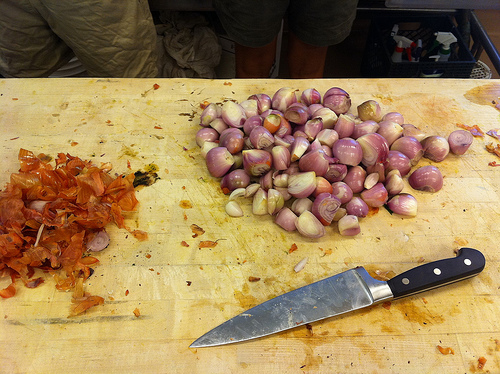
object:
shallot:
[449, 123, 471, 153]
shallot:
[293, 208, 324, 239]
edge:
[188, 265, 366, 346]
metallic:
[191, 263, 364, 351]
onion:
[287, 171, 320, 200]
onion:
[269, 85, 300, 110]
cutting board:
[0, 77, 500, 370]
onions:
[201, 143, 238, 179]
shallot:
[268, 110, 302, 138]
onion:
[339, 214, 362, 244]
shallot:
[333, 137, 364, 165]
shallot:
[448, 127, 473, 156]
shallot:
[388, 192, 419, 217]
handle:
[388, 246, 486, 300]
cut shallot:
[206, 146, 234, 178]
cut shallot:
[408, 165, 443, 193]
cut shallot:
[241, 148, 273, 177]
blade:
[185, 245, 485, 348]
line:
[156, 263, 189, 267]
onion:
[330, 134, 364, 169]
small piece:
[195, 238, 219, 249]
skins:
[63, 289, 106, 319]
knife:
[190, 243, 487, 350]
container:
[362, 11, 477, 79]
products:
[388, 23, 400, 38]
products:
[388, 32, 418, 63]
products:
[407, 37, 424, 62]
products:
[433, 29, 458, 62]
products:
[420, 53, 445, 77]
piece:
[205, 142, 237, 181]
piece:
[284, 102, 310, 129]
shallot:
[273, 82, 295, 104]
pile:
[192, 78, 479, 238]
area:
[178, 254, 401, 358]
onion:
[407, 163, 448, 195]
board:
[0, 77, 499, 374]